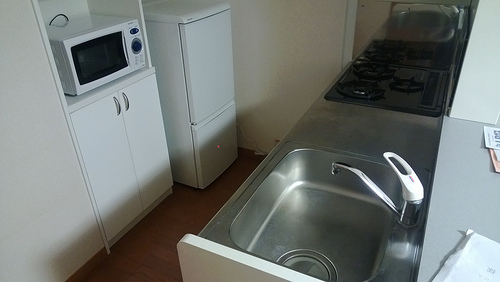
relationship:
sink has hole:
[230, 148, 412, 277] [285, 253, 329, 281]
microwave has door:
[45, 16, 151, 94] [72, 33, 128, 82]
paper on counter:
[430, 229, 498, 278] [418, 115, 499, 279]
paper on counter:
[482, 125, 499, 172] [418, 115, 499, 279]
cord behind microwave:
[49, 13, 70, 25] [45, 16, 151, 94]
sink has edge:
[230, 148, 412, 277] [175, 234, 315, 279]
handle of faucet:
[383, 151, 423, 201] [333, 149, 421, 230]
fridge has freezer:
[146, 3, 238, 189] [190, 105, 240, 179]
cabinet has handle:
[72, 76, 177, 241] [114, 97, 122, 116]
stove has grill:
[326, 59, 444, 113] [338, 78, 383, 101]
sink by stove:
[230, 148, 412, 277] [326, 59, 444, 113]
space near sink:
[297, 101, 444, 165] [230, 148, 412, 277]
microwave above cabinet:
[45, 16, 151, 94] [72, 76, 177, 241]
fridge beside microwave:
[146, 3, 238, 189] [45, 16, 151, 94]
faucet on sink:
[333, 149, 421, 230] [230, 148, 412, 277]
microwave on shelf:
[45, 16, 151, 94] [61, 71, 158, 109]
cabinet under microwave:
[72, 76, 177, 241] [45, 16, 151, 94]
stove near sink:
[326, 59, 444, 113] [230, 148, 412, 277]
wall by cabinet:
[231, 4, 346, 167] [72, 76, 177, 241]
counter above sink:
[418, 115, 499, 279] [230, 148, 412, 277]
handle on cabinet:
[114, 97, 122, 116] [72, 76, 177, 241]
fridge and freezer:
[146, 3, 238, 189] [190, 105, 240, 179]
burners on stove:
[341, 60, 420, 98] [326, 59, 444, 113]